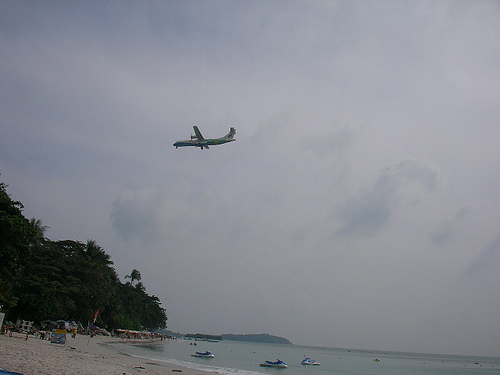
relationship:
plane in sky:
[171, 119, 255, 159] [279, 53, 380, 138]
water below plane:
[232, 339, 285, 364] [171, 119, 255, 159]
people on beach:
[41, 314, 70, 344] [70, 324, 122, 374]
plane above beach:
[171, 119, 255, 159] [70, 324, 122, 374]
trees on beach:
[46, 255, 118, 298] [70, 324, 122, 374]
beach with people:
[70, 324, 122, 374] [41, 314, 70, 344]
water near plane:
[232, 339, 285, 364] [171, 119, 255, 159]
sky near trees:
[279, 53, 380, 138] [46, 255, 118, 298]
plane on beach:
[171, 119, 255, 159] [70, 324, 122, 374]